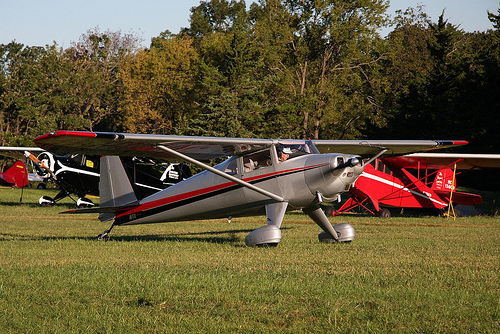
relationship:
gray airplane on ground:
[33, 114, 477, 267] [6, 244, 498, 330]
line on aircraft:
[106, 156, 330, 216] [32, 130, 467, 247]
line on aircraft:
[114, 171, 340, 224] [32, 130, 467, 247]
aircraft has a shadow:
[32, 130, 467, 247] [15, 210, 285, 269]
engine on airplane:
[324, 153, 388, 177] [20, 83, 454, 268]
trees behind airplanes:
[0, 0, 497, 131] [81, 97, 478, 247]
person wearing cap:
[277, 144, 293, 162] [282, 146, 292, 154]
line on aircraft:
[118, 160, 329, 223] [32, 130, 467, 247]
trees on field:
[7, 0, 497, 155] [1, 180, 498, 332]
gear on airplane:
[242, 220, 355, 247] [33, 101, 480, 273]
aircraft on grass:
[32, 130, 467, 247] [25, 238, 477, 325]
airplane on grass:
[334, 152, 485, 216] [25, 238, 477, 325]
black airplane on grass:
[34, 148, 194, 208] [25, 238, 477, 325]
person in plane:
[270, 139, 301, 164] [39, 62, 462, 271]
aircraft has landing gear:
[32, 130, 467, 247] [245, 202, 290, 247]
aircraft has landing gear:
[32, 130, 467, 247] [301, 205, 355, 241]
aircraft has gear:
[32, 130, 467, 247] [271, 201, 385, 255]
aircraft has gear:
[32, 130, 467, 247] [97, 220, 117, 245]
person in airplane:
[277, 144, 293, 162] [23, 73, 499, 288]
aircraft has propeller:
[32, 130, 467, 247] [315, 145, 383, 191]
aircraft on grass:
[32, 130, 467, 247] [2, 212, 498, 331]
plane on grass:
[345, 147, 484, 217] [2, 212, 498, 331]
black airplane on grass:
[34, 148, 194, 208] [2, 212, 498, 331]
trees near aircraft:
[0, 0, 497, 131] [32, 130, 467, 247]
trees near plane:
[0, 0, 497, 131] [332, 154, 498, 215]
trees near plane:
[0, 0, 497, 131] [0, 146, 190, 206]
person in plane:
[277, 144, 293, 162] [33, 117, 473, 262]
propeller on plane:
[18, 148, 58, 181] [17, 149, 192, 210]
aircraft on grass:
[32, 130, 467, 247] [0, 185, 498, 332]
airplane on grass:
[334, 152, 485, 216] [0, 185, 498, 332]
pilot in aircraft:
[279, 144, 297, 169] [32, 130, 467, 247]